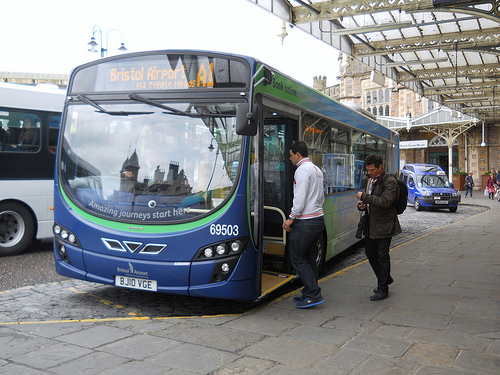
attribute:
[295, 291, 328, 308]
sneakers — blue, black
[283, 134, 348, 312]
man sweater — white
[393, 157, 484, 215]
car — blue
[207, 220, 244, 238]
number — in white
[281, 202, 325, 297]
jeans — blue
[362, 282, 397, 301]
shoes — black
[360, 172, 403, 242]
jacket — brown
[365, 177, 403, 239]
jacket — black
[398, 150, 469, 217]
van — blue 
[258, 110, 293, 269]
doors — open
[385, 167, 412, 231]
backpack — black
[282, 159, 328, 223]
sweater — white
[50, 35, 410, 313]
bus — long, blue